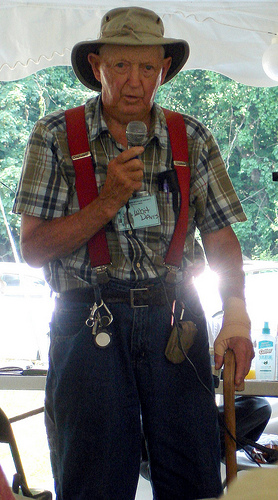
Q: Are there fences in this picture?
A: No, there are no fences.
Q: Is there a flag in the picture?
A: No, there are no flags.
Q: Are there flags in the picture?
A: No, there are no flags.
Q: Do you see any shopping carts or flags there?
A: No, there are no flags or shopping carts.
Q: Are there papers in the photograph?
A: No, there are no papers.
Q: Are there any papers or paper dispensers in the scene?
A: No, there are no papers or paper dispensers.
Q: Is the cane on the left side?
A: No, the cane is on the right of the image.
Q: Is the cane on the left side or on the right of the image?
A: The cane is on the right of the image.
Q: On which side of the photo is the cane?
A: The cane is on the right of the image.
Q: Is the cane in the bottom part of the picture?
A: Yes, the cane is in the bottom of the image.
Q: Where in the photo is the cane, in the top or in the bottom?
A: The cane is in the bottom of the image.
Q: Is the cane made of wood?
A: Yes, the cane is made of wood.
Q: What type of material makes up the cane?
A: The cane is made of wood.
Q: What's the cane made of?
A: The cane is made of wood.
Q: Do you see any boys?
A: No, there are no boys.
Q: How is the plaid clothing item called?
A: The clothing item is a shirt.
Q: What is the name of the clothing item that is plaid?
A: The clothing item is a shirt.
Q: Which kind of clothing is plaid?
A: The clothing is a shirt.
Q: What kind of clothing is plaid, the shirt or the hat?
A: The shirt is plaid.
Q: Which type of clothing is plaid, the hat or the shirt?
A: The shirt is plaid.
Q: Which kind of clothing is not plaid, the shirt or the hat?
A: The hat is not plaid.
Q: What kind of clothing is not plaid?
A: The clothing is a hat.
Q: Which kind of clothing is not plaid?
A: The clothing is a hat.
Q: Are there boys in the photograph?
A: No, there are no boys.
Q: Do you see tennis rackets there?
A: No, there are no tennis rackets.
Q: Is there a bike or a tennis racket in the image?
A: No, there are no rackets or bikes.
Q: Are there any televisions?
A: No, there are no televisions.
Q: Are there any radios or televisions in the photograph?
A: No, there are no televisions or radios.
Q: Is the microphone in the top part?
A: Yes, the microphone is in the top of the image.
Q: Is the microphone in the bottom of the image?
A: No, the microphone is in the top of the image.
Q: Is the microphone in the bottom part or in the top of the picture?
A: The microphone is in the top of the image.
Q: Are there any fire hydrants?
A: No, there are no fire hydrants.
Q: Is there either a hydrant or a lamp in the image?
A: No, there are no fire hydrants or lamps.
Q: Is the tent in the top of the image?
A: Yes, the tent is in the top of the image.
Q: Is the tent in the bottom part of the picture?
A: No, the tent is in the top of the image.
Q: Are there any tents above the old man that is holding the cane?
A: Yes, there is a tent above the man.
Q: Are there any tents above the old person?
A: Yes, there is a tent above the man.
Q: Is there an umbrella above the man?
A: No, there is a tent above the man.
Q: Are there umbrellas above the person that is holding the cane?
A: No, there is a tent above the man.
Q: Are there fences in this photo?
A: No, there are no fences.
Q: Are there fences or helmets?
A: No, there are no fences or helmets.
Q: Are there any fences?
A: No, there are no fences.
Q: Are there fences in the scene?
A: No, there are no fences.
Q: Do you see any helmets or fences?
A: No, there are no fences or helmets.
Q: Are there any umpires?
A: No, there are no umpires.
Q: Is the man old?
A: Yes, the man is old.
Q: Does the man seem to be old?
A: Yes, the man is old.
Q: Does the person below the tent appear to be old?
A: Yes, the man is old.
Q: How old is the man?
A: The man is old.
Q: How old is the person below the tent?
A: The man is old.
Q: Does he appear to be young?
A: No, the man is old.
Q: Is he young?
A: No, the man is old.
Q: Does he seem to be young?
A: No, the man is old.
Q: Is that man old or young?
A: The man is old.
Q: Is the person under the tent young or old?
A: The man is old.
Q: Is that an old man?
A: Yes, that is an old man.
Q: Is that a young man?
A: No, that is an old man.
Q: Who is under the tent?
A: The man is under the tent.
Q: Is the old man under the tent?
A: Yes, the man is under the tent.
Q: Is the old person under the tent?
A: Yes, the man is under the tent.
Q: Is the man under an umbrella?
A: No, the man is under the tent.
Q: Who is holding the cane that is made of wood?
A: The man is holding the cane.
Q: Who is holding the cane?
A: The man is holding the cane.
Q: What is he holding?
A: The man is holding the cane.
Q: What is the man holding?
A: The man is holding the cane.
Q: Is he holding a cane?
A: Yes, the man is holding a cane.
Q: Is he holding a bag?
A: No, the man is holding a cane.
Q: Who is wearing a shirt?
A: The man is wearing a shirt.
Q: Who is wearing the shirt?
A: The man is wearing a shirt.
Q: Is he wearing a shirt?
A: Yes, the man is wearing a shirt.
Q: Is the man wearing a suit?
A: No, the man is wearing a shirt.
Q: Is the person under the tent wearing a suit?
A: No, the man is wearing a shirt.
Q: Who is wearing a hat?
A: The man is wearing a hat.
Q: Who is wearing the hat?
A: The man is wearing a hat.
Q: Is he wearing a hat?
A: Yes, the man is wearing a hat.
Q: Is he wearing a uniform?
A: No, the man is wearing a hat.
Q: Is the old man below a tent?
A: Yes, the man is below a tent.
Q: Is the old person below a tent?
A: Yes, the man is below a tent.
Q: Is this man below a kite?
A: No, the man is below a tent.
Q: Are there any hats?
A: Yes, there is a hat.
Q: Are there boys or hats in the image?
A: Yes, there is a hat.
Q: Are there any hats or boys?
A: Yes, there is a hat.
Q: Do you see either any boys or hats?
A: Yes, there is a hat.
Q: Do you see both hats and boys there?
A: No, there is a hat but no boys.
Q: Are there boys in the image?
A: No, there are no boys.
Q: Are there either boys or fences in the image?
A: No, there are no boys or fences.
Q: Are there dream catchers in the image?
A: No, there are no dream catchers.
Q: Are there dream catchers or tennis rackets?
A: No, there are no dream catchers or tennis rackets.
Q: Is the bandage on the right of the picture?
A: Yes, the bandage is on the right of the image.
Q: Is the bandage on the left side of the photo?
A: No, the bandage is on the right of the image.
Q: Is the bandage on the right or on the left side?
A: The bandage is on the right of the image.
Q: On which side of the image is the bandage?
A: The bandage is on the right of the image.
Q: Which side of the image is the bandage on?
A: The bandage is on the right of the image.